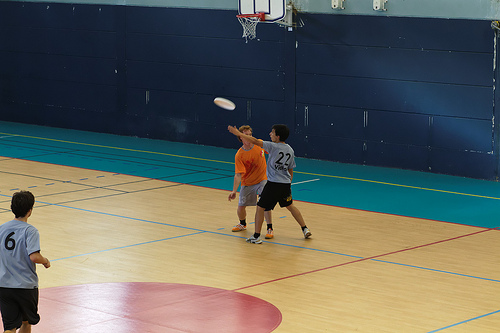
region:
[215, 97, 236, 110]
A frisbee is airborne.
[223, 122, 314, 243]
Two boys play with the frisbee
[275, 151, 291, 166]
The number 22 is on the boy's shirt.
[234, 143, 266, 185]
The boy's shirt is orange.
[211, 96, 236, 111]
The frisbee is white.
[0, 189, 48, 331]
A third boy watches.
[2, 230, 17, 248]
The number 6 is on the boy's shirt.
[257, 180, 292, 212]
The boy's shorts are black.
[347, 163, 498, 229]
The court is green.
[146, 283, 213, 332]
The court is red.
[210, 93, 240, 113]
Frisbee in the air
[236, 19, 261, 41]
Basketball hoop net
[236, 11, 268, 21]
Basketball hoop on backboard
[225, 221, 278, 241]
Orange sneakers on frisbee guard.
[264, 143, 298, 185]
Blue shirt with #22 on back.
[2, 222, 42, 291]
Blue shirt with #6 on back.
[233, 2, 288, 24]
Basketball backboard on wall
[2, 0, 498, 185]
Blue bleachers folded up flat against wall.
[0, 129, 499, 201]
Green boundary line painted on floor.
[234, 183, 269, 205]
Light blue shorts on frisbee guard.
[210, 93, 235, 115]
a white frisbee in the air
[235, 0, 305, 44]
a basketball hoop attached to the wall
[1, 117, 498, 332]
a basketball court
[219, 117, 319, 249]
two boys playing frisbee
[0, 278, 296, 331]
a large red circle on the gymnasium floor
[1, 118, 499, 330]
a wooden gymnasium floor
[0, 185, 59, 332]
a boy wearing a number 6 jersey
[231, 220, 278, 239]
orange sneakers on the boy's feet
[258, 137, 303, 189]
a gray number 22 shirt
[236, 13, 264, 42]
a basketball net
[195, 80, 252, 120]
a white frisbee in the air.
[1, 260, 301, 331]
a red spot on the ground.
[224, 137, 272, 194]
a person in an orange shirt.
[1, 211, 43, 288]
a man in a number 6 gray shirt.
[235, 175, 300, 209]
a man in black shorts.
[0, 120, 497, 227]
a section of a blue floor.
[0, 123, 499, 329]
a wood floor in a gym.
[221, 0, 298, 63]
a basket ball hoop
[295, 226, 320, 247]
a right shoe.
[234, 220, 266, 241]
a left shoe.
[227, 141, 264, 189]
The orange shirt the boy is wearing.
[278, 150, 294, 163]
The number 22 on the back of the boy's shirt.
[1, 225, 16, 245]
The number 6 on the back of the boy's shirt.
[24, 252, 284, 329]
The large red circle on the court.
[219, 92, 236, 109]
The white Frisbee in the air.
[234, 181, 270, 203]
The gray shorts the kid is wearing.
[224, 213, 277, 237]
The orange and gray sneakers the kid is wearing.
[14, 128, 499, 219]
The yellow line on the court.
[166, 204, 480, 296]
The red line on the court.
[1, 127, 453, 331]
The blue lines on the court.